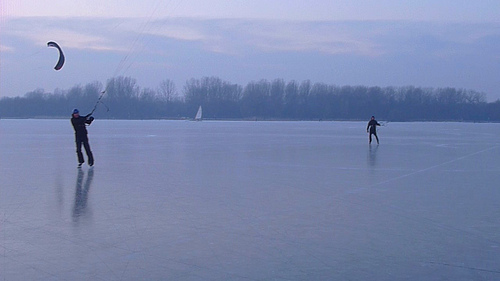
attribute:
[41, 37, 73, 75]
kite — blue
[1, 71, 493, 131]
trees — in lines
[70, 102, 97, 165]
person — closer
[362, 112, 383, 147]
person — skating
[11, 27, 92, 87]
kite — curved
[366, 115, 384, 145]
person — skating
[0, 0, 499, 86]
sky — greyish-blue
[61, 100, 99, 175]
person — skating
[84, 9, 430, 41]
clouds — white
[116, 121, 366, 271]
lake — frozen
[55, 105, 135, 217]
person — skating